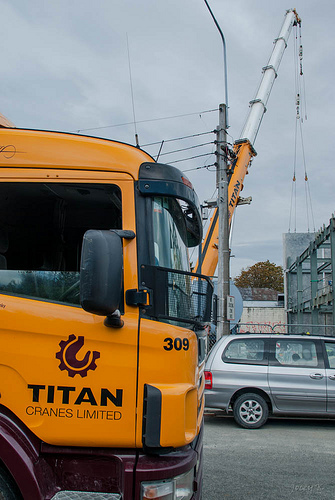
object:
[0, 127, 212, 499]
truck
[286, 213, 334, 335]
building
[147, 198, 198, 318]
window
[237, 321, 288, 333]
graffiti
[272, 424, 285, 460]
ground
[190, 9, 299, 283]
crane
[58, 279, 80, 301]
steering wheel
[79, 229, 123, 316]
mirror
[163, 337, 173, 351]
number 3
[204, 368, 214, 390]
taillight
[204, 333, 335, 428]
car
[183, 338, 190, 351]
number 9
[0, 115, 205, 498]
truck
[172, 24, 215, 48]
ground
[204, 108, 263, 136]
wall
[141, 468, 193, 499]
headlight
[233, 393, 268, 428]
tire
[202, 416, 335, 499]
asphalt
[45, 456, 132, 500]
step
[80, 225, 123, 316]
mirror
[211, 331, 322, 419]
van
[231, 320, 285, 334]
wall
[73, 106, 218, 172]
lines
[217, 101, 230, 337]
pole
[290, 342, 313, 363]
seats